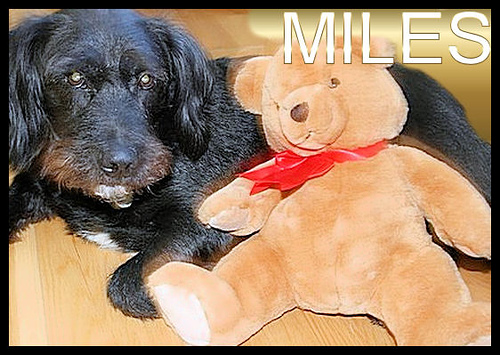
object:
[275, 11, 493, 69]
miles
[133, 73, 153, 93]
eye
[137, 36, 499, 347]
bear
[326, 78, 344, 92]
eye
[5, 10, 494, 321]
dog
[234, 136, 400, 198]
ribbon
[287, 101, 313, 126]
nose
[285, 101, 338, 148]
snout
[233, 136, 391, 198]
band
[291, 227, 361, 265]
fur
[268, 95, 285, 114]
eye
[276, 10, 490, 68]
name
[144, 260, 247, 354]
foot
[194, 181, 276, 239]
paw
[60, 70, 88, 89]
eye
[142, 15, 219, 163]
ear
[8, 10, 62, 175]
ear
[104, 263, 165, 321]
paw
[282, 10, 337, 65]
letter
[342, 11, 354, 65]
letter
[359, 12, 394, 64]
letter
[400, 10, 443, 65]
letter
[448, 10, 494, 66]
letter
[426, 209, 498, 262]
paw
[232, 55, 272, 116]
ear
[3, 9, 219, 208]
head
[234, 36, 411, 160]
head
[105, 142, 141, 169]
nose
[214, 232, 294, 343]
leg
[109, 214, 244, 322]
leg